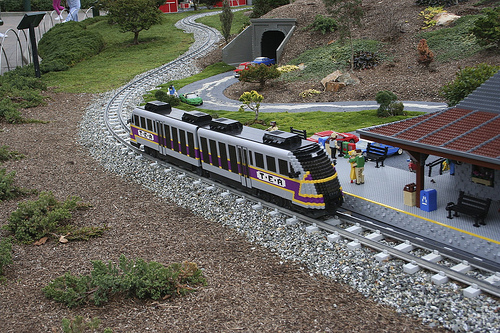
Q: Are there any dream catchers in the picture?
A: No, there are no dream catchers.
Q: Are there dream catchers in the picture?
A: No, there are no dream catchers.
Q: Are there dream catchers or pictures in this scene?
A: No, there are no dream catchers or pictures.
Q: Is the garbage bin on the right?
A: Yes, the garbage bin is on the right of the image.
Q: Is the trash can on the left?
A: No, the trash can is on the right of the image.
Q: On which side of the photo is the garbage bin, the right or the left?
A: The garbage bin is on the right of the image.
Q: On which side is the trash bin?
A: The trash bin is on the right of the image.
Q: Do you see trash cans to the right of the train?
A: Yes, there is a trash can to the right of the train.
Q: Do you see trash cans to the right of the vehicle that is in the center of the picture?
A: Yes, there is a trash can to the right of the train.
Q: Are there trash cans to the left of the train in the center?
A: No, the trash can is to the right of the train.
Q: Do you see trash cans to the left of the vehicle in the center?
A: No, the trash can is to the right of the train.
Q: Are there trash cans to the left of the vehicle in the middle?
A: No, the trash can is to the right of the train.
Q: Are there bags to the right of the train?
A: No, there is a trash can to the right of the train.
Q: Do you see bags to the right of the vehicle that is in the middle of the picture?
A: No, there is a trash can to the right of the train.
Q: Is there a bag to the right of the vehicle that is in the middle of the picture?
A: No, there is a trash can to the right of the train.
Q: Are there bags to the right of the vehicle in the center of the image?
A: No, there is a trash can to the right of the train.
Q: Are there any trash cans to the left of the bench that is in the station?
A: Yes, there is a trash can to the left of the bench.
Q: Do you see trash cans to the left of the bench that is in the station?
A: Yes, there is a trash can to the left of the bench.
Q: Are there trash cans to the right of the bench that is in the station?
A: No, the trash can is to the left of the bench.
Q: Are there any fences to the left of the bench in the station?
A: No, there is a trash can to the left of the bench.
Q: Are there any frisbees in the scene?
A: No, there are no frisbees.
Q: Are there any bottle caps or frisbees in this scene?
A: No, there are no frisbees or bottle caps.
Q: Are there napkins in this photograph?
A: No, there are no napkins.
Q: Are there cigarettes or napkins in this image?
A: No, there are no napkins or cigarettes.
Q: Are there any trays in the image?
A: No, there are no trays.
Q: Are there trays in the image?
A: No, there are no trays.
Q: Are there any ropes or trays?
A: No, there are no trays or ropes.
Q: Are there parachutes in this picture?
A: No, there are no parachutes.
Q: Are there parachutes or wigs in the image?
A: No, there are no parachutes or wigs.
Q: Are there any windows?
A: Yes, there is a window.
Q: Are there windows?
A: Yes, there is a window.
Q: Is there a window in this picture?
A: Yes, there is a window.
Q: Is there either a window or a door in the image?
A: Yes, there is a window.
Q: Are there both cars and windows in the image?
A: Yes, there are both a window and a car.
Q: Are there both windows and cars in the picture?
A: Yes, there are both a window and a car.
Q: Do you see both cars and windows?
A: Yes, there are both a window and a car.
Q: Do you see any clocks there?
A: No, there are no clocks.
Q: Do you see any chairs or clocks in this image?
A: No, there are no clocks or chairs.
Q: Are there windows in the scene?
A: Yes, there is a window.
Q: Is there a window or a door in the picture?
A: Yes, there is a window.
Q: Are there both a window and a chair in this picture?
A: No, there is a window but no chairs.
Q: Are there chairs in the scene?
A: No, there are no chairs.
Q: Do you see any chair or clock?
A: No, there are no chairs or clocks.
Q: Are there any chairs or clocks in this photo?
A: No, there are no chairs or clocks.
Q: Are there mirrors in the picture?
A: No, there are no mirrors.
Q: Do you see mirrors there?
A: No, there are no mirrors.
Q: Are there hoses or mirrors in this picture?
A: No, there are no mirrors or hoses.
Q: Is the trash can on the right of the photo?
A: Yes, the trash can is on the right of the image.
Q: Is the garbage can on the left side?
A: No, the garbage can is on the right of the image.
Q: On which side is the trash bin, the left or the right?
A: The trash bin is on the right of the image.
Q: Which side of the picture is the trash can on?
A: The trash can is on the right of the image.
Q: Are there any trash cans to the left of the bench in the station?
A: Yes, there is a trash can to the left of the bench.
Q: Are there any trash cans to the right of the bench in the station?
A: No, the trash can is to the left of the bench.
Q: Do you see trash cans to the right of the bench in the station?
A: No, the trash can is to the left of the bench.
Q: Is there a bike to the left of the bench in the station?
A: No, there is a trash can to the left of the bench.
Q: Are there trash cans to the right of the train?
A: Yes, there is a trash can to the right of the train.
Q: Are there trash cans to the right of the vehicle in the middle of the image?
A: Yes, there is a trash can to the right of the train.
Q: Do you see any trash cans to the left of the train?
A: No, the trash can is to the right of the train.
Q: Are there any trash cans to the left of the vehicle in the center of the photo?
A: No, the trash can is to the right of the train.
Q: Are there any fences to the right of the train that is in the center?
A: No, there is a trash can to the right of the train.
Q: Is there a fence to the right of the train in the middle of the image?
A: No, there is a trash can to the right of the train.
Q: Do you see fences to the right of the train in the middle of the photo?
A: No, there is a trash can to the right of the train.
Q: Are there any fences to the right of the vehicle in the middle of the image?
A: No, there is a trash can to the right of the train.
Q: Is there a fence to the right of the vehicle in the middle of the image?
A: No, there is a trash can to the right of the train.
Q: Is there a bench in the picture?
A: Yes, there is a bench.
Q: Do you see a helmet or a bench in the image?
A: Yes, there is a bench.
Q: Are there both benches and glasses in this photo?
A: No, there is a bench but no glasses.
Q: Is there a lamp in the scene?
A: No, there are no lamps.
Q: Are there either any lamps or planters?
A: No, there are no lamps or planters.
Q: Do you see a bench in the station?
A: Yes, there is a bench in the station.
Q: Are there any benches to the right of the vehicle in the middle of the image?
A: Yes, there is a bench to the right of the train.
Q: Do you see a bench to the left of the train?
A: No, the bench is to the right of the train.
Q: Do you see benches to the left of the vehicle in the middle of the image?
A: No, the bench is to the right of the train.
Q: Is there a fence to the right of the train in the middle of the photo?
A: No, there is a bench to the right of the train.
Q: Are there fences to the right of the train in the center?
A: No, there is a bench to the right of the train.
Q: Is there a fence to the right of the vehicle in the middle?
A: No, there is a bench to the right of the train.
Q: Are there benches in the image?
A: Yes, there is a bench.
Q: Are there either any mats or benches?
A: Yes, there is a bench.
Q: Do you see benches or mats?
A: Yes, there is a bench.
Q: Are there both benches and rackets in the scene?
A: No, there is a bench but no rackets.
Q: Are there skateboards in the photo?
A: No, there are no skateboards.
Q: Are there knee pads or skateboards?
A: No, there are no skateboards or knee pads.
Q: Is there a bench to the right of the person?
A: Yes, there is a bench to the right of the person.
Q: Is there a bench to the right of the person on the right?
A: Yes, there is a bench to the right of the person.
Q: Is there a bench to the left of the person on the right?
A: No, the bench is to the right of the person.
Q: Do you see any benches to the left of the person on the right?
A: No, the bench is to the right of the person.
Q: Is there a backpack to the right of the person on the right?
A: No, there is a bench to the right of the person.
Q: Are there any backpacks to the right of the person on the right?
A: No, there is a bench to the right of the person.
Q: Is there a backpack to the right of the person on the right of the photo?
A: No, there is a bench to the right of the person.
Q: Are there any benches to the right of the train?
A: Yes, there is a bench to the right of the train.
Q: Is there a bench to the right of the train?
A: Yes, there is a bench to the right of the train.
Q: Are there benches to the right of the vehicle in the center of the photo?
A: Yes, there is a bench to the right of the train.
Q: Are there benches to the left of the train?
A: No, the bench is to the right of the train.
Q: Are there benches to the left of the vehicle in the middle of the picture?
A: No, the bench is to the right of the train.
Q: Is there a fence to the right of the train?
A: No, there is a bench to the right of the train.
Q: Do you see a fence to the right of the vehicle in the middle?
A: No, there is a bench to the right of the train.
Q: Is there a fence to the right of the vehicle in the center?
A: No, there is a bench to the right of the train.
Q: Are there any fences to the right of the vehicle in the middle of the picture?
A: No, there is a bench to the right of the train.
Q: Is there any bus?
A: No, there are no buses.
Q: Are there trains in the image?
A: Yes, there is a train.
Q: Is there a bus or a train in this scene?
A: Yes, there is a train.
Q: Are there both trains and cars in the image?
A: Yes, there are both a train and a car.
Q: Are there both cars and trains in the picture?
A: Yes, there are both a train and a car.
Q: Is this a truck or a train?
A: This is a train.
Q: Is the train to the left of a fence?
A: No, the train is to the left of the bench.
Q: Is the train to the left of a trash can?
A: Yes, the train is to the left of a trash can.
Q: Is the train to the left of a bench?
A: Yes, the train is to the left of a bench.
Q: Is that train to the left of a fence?
A: No, the train is to the left of a bench.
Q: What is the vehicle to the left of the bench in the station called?
A: The vehicle is a train.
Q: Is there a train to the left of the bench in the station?
A: Yes, there is a train to the left of the bench.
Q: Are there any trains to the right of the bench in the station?
A: No, the train is to the left of the bench.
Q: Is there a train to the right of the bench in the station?
A: No, the train is to the left of the bench.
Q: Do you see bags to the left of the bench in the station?
A: No, there is a train to the left of the bench.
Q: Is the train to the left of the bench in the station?
A: Yes, the train is to the left of the bench.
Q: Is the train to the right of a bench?
A: No, the train is to the left of a bench.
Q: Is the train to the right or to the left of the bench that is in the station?
A: The train is to the left of the bench.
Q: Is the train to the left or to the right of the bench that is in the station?
A: The train is to the left of the bench.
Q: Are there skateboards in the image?
A: No, there are no skateboards.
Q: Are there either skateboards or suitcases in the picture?
A: No, there are no skateboards or suitcases.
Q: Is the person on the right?
A: Yes, the person is on the right of the image.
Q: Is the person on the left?
A: No, the person is on the right of the image.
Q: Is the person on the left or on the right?
A: The person is on the right of the image.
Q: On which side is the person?
A: The person is on the right of the image.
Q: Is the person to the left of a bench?
A: Yes, the person is to the left of a bench.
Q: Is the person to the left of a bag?
A: No, the person is to the left of a bench.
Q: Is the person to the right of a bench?
A: No, the person is to the left of a bench.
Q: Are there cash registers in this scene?
A: No, there are no cash registers.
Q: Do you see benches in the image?
A: Yes, there is a bench.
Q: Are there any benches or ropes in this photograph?
A: Yes, there is a bench.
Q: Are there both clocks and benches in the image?
A: No, there is a bench but no clocks.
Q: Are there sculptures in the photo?
A: No, there are no sculptures.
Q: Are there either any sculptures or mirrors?
A: No, there are no sculptures or mirrors.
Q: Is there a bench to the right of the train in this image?
A: Yes, there is a bench to the right of the train.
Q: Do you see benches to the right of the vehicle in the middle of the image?
A: Yes, there is a bench to the right of the train.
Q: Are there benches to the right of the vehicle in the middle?
A: Yes, there is a bench to the right of the train.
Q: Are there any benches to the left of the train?
A: No, the bench is to the right of the train.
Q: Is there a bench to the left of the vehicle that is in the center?
A: No, the bench is to the right of the train.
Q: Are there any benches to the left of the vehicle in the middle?
A: No, the bench is to the right of the train.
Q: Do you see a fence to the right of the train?
A: No, there is a bench to the right of the train.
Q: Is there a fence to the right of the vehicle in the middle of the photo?
A: No, there is a bench to the right of the train.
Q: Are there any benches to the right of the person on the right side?
A: Yes, there is a bench to the right of the person.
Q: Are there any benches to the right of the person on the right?
A: Yes, there is a bench to the right of the person.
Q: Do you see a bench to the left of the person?
A: No, the bench is to the right of the person.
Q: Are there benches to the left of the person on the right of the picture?
A: No, the bench is to the right of the person.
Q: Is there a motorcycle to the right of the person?
A: No, there is a bench to the right of the person.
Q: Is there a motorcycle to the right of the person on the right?
A: No, there is a bench to the right of the person.